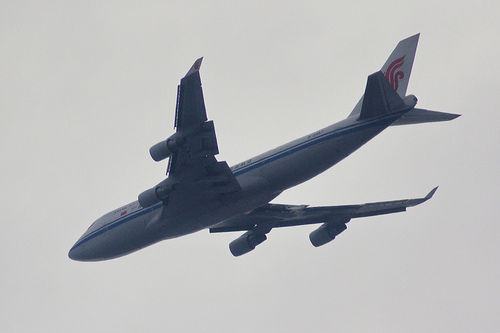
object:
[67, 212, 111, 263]
front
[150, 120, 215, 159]
turbine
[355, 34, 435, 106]
wing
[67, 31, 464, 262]
plane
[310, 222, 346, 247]
turbine